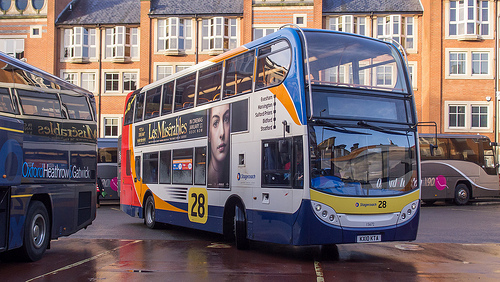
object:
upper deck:
[122, 30, 420, 132]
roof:
[56, 2, 140, 24]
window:
[446, 49, 468, 78]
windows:
[445, 47, 496, 77]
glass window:
[470, 51, 487, 74]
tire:
[19, 195, 51, 259]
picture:
[206, 101, 231, 188]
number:
[184, 186, 211, 223]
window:
[449, 0, 489, 34]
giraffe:
[66, 231, 149, 271]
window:
[303, 40, 398, 88]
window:
[447, 106, 469, 131]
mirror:
[273, 111, 293, 143]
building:
[0, 1, 484, 196]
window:
[466, 97, 493, 134]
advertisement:
[132, 109, 219, 149]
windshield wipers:
[358, 120, 411, 137]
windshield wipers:
[316, 119, 371, 136]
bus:
[115, 22, 422, 259]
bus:
[7, 46, 102, 258]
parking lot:
[107, 164, 496, 277]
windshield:
[300, 30, 408, 95]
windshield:
[311, 121, 418, 196]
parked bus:
[2, 39, 102, 262]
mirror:
[286, 137, 307, 180]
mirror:
[295, 23, 416, 140]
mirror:
[414, 120, 440, 155]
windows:
[51, 22, 147, 102]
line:
[23, 235, 153, 280]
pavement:
[0, 227, 499, 279]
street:
[8, 164, 498, 280]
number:
[372, 190, 393, 210]